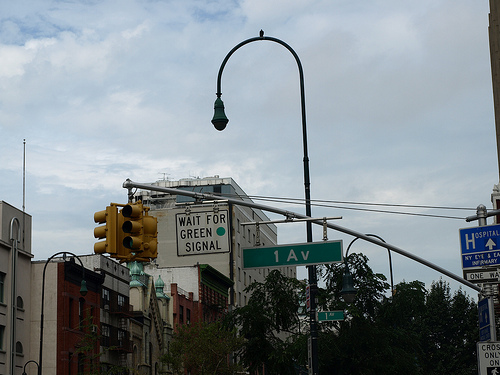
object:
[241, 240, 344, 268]
sign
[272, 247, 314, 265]
1 av.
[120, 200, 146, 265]
light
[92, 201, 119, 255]
light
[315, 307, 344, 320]
sign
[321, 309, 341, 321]
number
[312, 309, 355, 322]
sign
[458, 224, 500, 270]
sign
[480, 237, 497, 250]
arrow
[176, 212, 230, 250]
sign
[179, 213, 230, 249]
lettering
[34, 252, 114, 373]
building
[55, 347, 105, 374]
story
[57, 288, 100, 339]
story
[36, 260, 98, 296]
story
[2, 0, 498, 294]
sky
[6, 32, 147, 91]
cloud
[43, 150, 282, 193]
cloud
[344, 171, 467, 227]
cloud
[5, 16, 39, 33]
spot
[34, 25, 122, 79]
spot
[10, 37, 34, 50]
spot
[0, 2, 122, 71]
left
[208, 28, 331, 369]
pole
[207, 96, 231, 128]
light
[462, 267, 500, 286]
sign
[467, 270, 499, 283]
right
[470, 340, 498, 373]
sign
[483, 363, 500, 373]
pedestrian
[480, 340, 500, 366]
instructions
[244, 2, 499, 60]
cloud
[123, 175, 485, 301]
pole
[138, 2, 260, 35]
cloud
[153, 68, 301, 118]
cloud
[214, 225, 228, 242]
dot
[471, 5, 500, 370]
street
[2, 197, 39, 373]
building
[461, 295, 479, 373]
tree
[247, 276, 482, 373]
distance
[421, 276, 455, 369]
tree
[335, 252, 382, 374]
tree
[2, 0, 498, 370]
town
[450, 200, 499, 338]
post